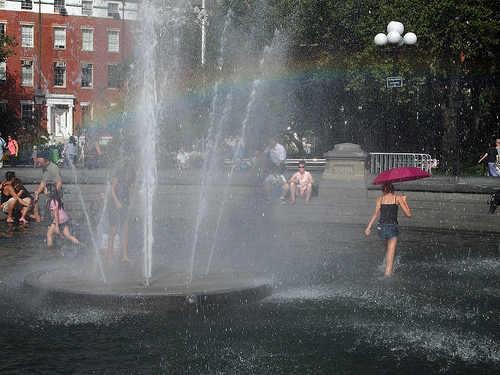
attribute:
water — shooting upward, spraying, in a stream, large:
[63, 6, 318, 284]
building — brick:
[4, 3, 190, 169]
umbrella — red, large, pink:
[372, 161, 431, 186]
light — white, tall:
[373, 16, 419, 138]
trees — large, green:
[185, 9, 499, 165]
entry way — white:
[45, 92, 74, 141]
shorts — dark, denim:
[55, 221, 68, 231]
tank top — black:
[375, 198, 399, 215]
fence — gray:
[363, 146, 427, 178]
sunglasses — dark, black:
[298, 166, 304, 171]